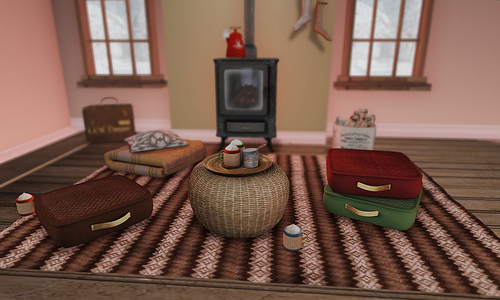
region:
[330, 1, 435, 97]
window on the wall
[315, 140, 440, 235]
two suitcases stacked on top of each other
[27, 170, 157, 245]
brown suitcase with a gold handle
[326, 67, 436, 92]
brown windowsill under the window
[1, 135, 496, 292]
rug on the floor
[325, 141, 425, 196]
a deep red suitcase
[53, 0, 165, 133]
pink paint on the wall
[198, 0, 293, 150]
fireplace against the wall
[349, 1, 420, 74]
brown lines on the window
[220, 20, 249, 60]
something red on top of the fireplace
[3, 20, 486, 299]
a cozy spot on the floor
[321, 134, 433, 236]
a green & a red pillow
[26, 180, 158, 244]
a brown pillow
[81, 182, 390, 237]
all the pillows appear to have golden handles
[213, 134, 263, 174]
the cups appear full of something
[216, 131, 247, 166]
maybe whipped cream?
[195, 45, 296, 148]
the wood stove is a nice touch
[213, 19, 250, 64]
a red kettle sets atop the stove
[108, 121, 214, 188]
a folded up blanket & a pillow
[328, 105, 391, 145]
a box of kindling & wood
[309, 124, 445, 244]
Two suitcases on a rug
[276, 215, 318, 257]
A cup with whip cream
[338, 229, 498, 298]
A brown floor rug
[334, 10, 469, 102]
A window with a brown wooden frame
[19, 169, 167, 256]
A brown suitcase on a rug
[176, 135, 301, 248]
A brown ottoman with coffee cups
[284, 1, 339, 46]
A person's feet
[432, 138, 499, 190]
A brown hardwood floor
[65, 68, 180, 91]
A brown wooden window sill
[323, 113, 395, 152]
A white cardboard box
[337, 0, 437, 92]
a window in a room.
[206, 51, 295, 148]
stove between two windows.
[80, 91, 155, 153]
a basket under a window.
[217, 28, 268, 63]
a red tea kettle on a stove.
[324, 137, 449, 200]
a large red item.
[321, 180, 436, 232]
a large green item.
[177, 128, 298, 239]
a large brown basket.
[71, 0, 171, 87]
a window to the left of a stove.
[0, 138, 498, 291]
a striped rug on the ground.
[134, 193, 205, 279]
A white stripe on a rug.